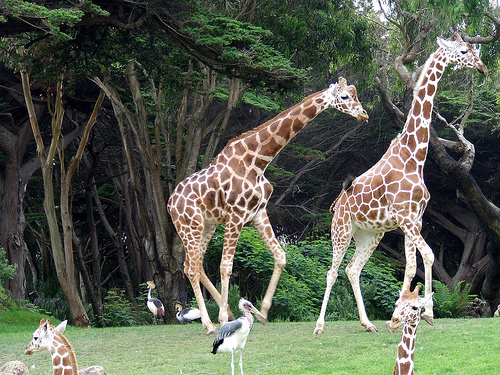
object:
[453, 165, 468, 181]
bark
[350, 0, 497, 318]
tree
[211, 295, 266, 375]
bird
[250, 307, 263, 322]
beak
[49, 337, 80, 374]
neck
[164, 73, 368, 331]
giraffe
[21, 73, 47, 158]
limbs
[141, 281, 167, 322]
bird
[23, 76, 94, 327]
bar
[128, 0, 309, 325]
trees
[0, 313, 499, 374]
grass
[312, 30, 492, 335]
giraffe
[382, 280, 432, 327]
head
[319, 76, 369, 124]
head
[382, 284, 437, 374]
giraffe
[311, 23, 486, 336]
giraffe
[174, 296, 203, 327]
bird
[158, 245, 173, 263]
bark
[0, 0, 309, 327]
tree